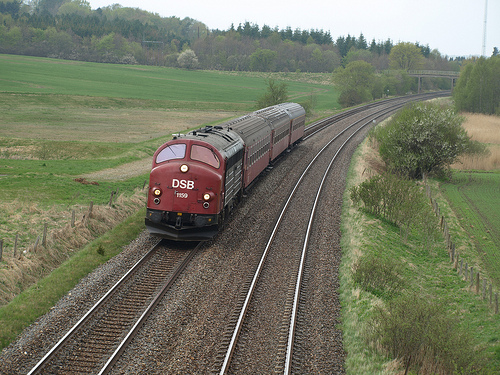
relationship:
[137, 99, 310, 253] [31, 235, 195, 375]
train moving on track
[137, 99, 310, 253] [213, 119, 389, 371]
train next to track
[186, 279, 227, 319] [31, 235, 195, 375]
pebbles between track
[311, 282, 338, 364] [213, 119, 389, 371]
pebbles next to track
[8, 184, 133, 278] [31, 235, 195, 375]
fence next to track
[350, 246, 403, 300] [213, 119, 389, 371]
bush next to track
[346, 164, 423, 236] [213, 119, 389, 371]
bush next to track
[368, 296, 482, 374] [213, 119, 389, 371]
bush next to track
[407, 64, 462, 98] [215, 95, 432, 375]
overpass above track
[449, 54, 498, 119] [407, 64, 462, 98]
trees next to overpass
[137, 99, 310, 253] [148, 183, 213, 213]
train has headlights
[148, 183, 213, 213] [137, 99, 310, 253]
headlights on front of train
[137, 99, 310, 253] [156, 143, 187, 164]
train has window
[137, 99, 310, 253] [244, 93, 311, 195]
train has cars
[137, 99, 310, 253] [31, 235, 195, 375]
train on a track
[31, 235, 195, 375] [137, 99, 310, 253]
track in front of train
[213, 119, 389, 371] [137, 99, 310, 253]
track next to train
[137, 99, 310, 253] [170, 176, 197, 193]
train has letters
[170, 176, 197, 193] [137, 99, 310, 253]
letters on front of train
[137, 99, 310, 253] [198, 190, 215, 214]
train has light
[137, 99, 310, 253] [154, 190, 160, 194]
train has headlights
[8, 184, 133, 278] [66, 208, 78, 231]
fence has post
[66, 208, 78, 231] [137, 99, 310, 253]
post next to train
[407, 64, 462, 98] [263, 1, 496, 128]
overpass in background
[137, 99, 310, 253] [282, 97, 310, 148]
train has car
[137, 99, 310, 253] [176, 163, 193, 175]
train has headlight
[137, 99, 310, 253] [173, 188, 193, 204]
train has numbers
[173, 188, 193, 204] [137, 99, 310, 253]
numbers on front of train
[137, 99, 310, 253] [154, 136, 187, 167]
train has window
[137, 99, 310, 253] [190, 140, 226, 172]
train has window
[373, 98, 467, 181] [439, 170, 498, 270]
tree next to crops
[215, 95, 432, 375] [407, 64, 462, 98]
track curves under overpass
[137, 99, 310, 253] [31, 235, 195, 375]
train on track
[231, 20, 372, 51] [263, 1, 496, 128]
trees in background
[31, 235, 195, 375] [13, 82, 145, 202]
track near field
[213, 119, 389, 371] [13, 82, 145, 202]
track near field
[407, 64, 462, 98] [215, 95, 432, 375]
overpass over track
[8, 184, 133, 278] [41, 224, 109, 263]
fence over grass